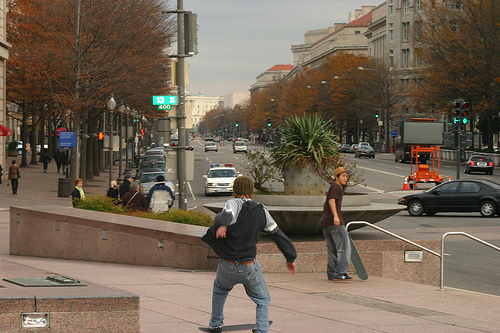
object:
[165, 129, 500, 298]
busy street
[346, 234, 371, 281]
skate board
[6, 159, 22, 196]
person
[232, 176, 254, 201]
hair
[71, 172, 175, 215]
group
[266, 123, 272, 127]
lights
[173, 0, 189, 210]
pole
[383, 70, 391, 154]
pole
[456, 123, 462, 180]
pole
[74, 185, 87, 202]
scarf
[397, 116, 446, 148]
construction sign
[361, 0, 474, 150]
building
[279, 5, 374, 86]
building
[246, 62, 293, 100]
building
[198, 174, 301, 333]
kid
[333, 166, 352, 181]
tan hat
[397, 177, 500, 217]
car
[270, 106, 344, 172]
bush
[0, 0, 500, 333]
city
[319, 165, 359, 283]
man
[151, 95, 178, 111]
street signs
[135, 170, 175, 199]
cars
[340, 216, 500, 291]
railings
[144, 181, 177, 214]
jacket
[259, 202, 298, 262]
arm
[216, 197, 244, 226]
arm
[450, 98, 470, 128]
stoplight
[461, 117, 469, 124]
light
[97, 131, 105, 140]
lights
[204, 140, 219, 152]
cars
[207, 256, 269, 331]
blue jeans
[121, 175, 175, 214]
two people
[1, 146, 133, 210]
sidewalk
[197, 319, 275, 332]
skate board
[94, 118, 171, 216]
curb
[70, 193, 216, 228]
planter